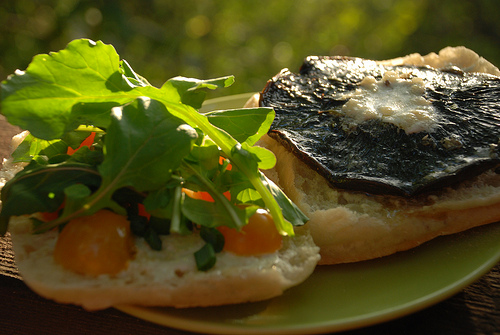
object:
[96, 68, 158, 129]
greens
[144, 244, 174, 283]
bread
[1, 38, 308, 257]
lettuce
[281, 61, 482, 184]
mushroom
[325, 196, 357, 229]
bread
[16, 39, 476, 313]
sandwich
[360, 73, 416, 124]
base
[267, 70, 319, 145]
mushroom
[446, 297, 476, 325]
table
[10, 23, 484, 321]
plate